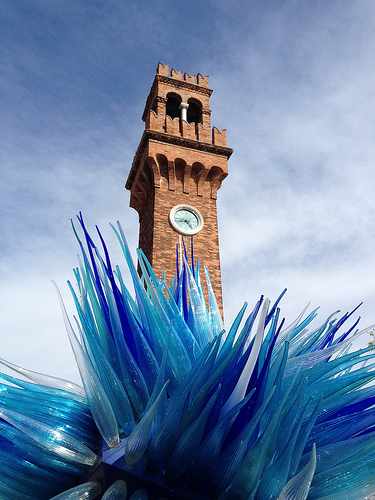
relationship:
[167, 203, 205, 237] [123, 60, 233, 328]
clock on building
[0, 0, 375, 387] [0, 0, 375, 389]
clouds in sky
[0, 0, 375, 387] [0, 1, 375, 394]
clouds in sky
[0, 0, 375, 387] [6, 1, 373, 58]
clouds in sky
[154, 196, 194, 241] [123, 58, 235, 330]
clock on clock tower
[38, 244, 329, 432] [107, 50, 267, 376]
blue flower in front of tower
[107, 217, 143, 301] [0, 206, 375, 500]
petal on blue flower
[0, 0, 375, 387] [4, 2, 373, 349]
clouds in sky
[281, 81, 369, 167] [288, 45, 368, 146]
clouds in sky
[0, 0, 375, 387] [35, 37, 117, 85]
clouds in blue sky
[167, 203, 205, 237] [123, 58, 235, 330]
clock on clock tower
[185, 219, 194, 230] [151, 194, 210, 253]
hand on clock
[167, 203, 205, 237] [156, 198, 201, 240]
clock on building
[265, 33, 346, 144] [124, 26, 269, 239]
sky behind tower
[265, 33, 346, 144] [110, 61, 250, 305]
sky behind tower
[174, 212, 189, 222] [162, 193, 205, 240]
hand of a clock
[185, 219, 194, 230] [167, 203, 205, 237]
hand on clock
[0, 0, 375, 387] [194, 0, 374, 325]
clouds in sky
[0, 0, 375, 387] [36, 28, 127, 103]
clouds in sky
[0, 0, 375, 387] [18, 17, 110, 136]
clouds in sky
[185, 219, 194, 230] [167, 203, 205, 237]
hand are on clock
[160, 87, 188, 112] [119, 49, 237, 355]
arch in tower